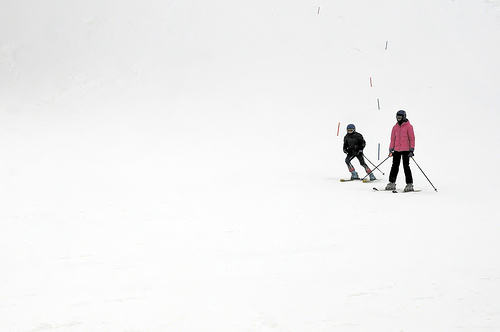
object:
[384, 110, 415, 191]
kid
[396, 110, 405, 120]
skully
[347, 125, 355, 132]
skully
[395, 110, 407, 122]
head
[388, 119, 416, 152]
jacket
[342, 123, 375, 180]
person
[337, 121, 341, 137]
pole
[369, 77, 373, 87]
pole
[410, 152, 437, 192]
ski poles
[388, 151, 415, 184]
pants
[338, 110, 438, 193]
two skiers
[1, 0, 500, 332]
snow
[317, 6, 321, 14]
poles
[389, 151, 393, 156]
glove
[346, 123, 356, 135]
head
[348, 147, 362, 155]
torso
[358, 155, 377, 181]
left leg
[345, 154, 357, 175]
right leg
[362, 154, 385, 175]
pole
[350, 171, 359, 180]
shoes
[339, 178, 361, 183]
skis